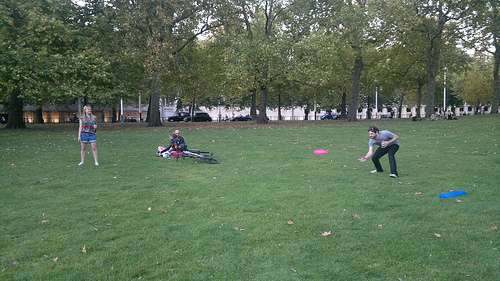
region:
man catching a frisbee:
[293, 111, 405, 183]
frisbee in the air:
[437, 173, 472, 212]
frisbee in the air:
[304, 135, 332, 162]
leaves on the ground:
[306, 206, 377, 243]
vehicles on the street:
[168, 107, 359, 124]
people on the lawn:
[421, 105, 465, 130]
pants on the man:
[362, 146, 407, 166]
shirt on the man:
[368, 132, 397, 144]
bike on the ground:
[178, 145, 223, 168]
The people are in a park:
[20, 32, 480, 253]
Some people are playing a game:
[5, 60, 463, 245]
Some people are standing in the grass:
[30, 51, 477, 253]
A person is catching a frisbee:
[23, 33, 464, 274]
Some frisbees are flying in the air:
[30, 77, 476, 250]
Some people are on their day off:
[20, 83, 490, 256]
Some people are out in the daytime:
[8, 67, 468, 248]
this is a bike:
[162, 138, 230, 168]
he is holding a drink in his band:
[347, 107, 424, 199]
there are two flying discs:
[283, 121, 496, 233]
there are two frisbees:
[275, 129, 493, 205]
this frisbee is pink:
[297, 136, 362, 166]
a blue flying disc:
[420, 175, 482, 205]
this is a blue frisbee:
[431, 179, 478, 216]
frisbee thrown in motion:
[310, 141, 330, 163]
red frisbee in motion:
[304, 140, 331, 168]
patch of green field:
[154, 190, 321, 242]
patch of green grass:
[98, 190, 285, 250]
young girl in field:
[53, 93, 121, 176]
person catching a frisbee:
[303, 118, 417, 192]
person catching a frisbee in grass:
[296, 118, 427, 195]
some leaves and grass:
[276, 200, 391, 248]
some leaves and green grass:
[189, 195, 386, 256]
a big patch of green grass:
[225, 180, 344, 260]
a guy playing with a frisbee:
[301, 126, 408, 188]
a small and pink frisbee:
[306, 133, 340, 160]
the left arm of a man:
[374, 127, 401, 147]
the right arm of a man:
[350, 140, 373, 165]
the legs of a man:
[366, 152, 408, 173]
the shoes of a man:
[372, 165, 401, 181]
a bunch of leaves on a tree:
[40, 32, 121, 83]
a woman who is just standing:
[66, 105, 107, 165]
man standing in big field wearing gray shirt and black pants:
[356, 124, 404, 179]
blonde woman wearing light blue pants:
[74, 101, 103, 168]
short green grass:
[0, 113, 495, 275]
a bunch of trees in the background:
[6, 3, 498, 128]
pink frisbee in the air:
[311, 142, 330, 157]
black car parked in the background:
[168, 110, 214, 125]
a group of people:
[65, 98, 437, 185]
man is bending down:
[355, 115, 411, 176]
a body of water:
[0, 95, 455, 116]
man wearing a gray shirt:
[362, 122, 399, 156]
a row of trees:
[23, 5, 455, 120]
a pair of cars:
[162, 102, 214, 127]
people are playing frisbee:
[71, 97, 403, 182]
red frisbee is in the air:
[305, 145, 326, 155]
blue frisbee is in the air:
[436, 178, 464, 203]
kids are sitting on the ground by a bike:
[153, 126, 212, 162]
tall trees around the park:
[0, 0, 498, 115]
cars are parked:
[163, 108, 265, 121]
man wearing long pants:
[364, 120, 399, 173]